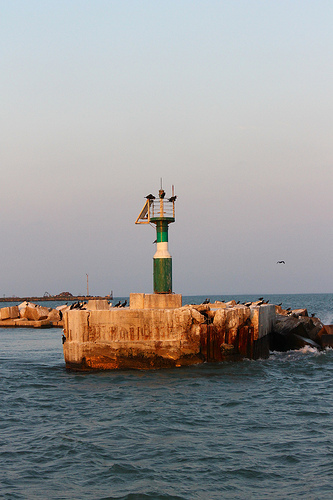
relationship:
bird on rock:
[114, 299, 124, 306] [74, 313, 212, 372]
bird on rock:
[200, 297, 208, 304] [74, 313, 212, 372]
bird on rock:
[293, 311, 303, 316] [74, 313, 212, 372]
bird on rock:
[70, 300, 80, 308] [74, 313, 212, 372]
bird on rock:
[244, 298, 251, 306] [74, 313, 212, 372]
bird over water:
[273, 257, 296, 271] [11, 378, 323, 494]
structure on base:
[154, 224, 179, 296] [133, 294, 181, 310]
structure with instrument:
[154, 224, 179, 296] [137, 204, 151, 222]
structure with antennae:
[154, 224, 179, 296] [159, 178, 167, 191]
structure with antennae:
[154, 224, 179, 296] [172, 183, 179, 194]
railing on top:
[149, 204, 179, 218] [159, 224, 165, 230]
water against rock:
[11, 378, 323, 494] [4, 300, 61, 329]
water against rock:
[11, 378, 323, 494] [280, 322, 325, 344]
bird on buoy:
[145, 194, 153, 199] [137, 179, 182, 302]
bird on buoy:
[158, 195, 163, 197] [137, 179, 182, 302]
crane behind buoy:
[85, 268, 95, 297] [137, 179, 182, 302]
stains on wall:
[81, 349, 232, 368] [79, 317, 266, 363]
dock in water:
[137, 179, 182, 302] [11, 378, 323, 494]